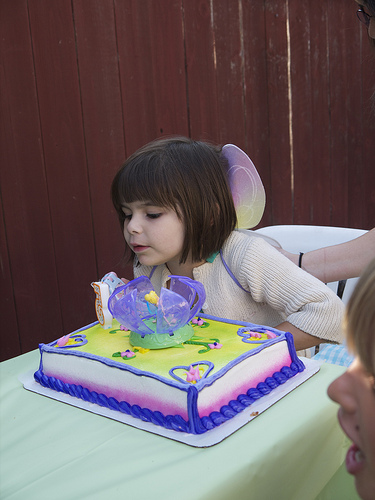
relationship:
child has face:
[109, 133, 349, 356] [117, 198, 182, 270]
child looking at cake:
[109, 133, 349, 356] [31, 267, 308, 439]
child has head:
[109, 133, 349, 356] [109, 135, 241, 272]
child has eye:
[109, 133, 349, 356] [141, 205, 167, 225]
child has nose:
[109, 133, 349, 356] [124, 215, 143, 238]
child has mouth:
[109, 133, 349, 356] [127, 239, 154, 256]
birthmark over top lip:
[351, 418, 365, 437] [335, 406, 364, 462]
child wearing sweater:
[109, 133, 349, 356] [126, 232, 346, 349]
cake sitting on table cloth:
[31, 267, 308, 439] [1, 345, 353, 500]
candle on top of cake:
[89, 269, 131, 329] [31, 267, 308, 439]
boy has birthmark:
[323, 259, 372, 499] [351, 418, 365, 437]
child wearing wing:
[109, 133, 349, 356] [216, 136, 270, 236]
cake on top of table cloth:
[31, 267, 308, 439] [1, 345, 353, 500]